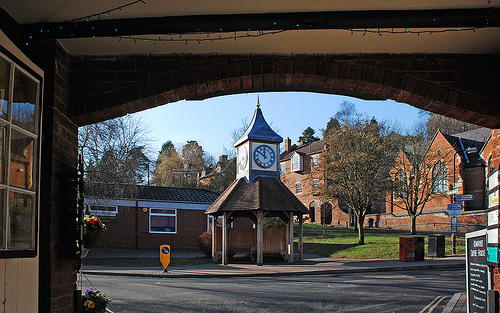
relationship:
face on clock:
[255, 136, 275, 169] [253, 138, 279, 172]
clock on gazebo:
[253, 138, 279, 172] [222, 113, 306, 266]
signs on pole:
[441, 183, 475, 253] [450, 229, 466, 256]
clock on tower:
[253, 138, 279, 172] [241, 110, 286, 190]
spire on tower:
[251, 85, 269, 109] [241, 110, 286, 190]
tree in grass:
[383, 149, 458, 250] [311, 214, 429, 258]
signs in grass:
[441, 183, 475, 253] [311, 214, 429, 258]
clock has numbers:
[253, 138, 279, 172] [257, 143, 270, 166]